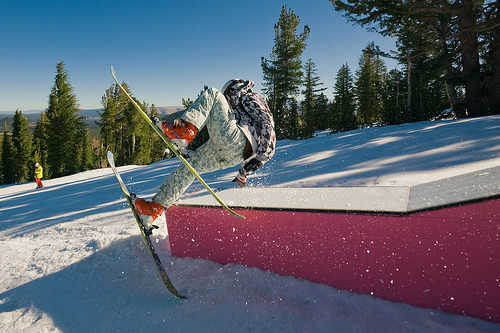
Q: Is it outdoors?
A: Yes, it is outdoors.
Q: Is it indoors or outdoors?
A: It is outdoors.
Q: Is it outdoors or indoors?
A: It is outdoors.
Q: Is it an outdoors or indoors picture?
A: It is outdoors.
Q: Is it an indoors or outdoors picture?
A: It is outdoors.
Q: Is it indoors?
A: No, it is outdoors.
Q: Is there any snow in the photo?
A: Yes, there is snow.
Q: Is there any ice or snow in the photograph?
A: Yes, there is snow.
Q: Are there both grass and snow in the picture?
A: No, there is snow but no grass.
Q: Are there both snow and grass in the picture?
A: No, there is snow but no grass.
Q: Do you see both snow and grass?
A: No, there is snow but no grass.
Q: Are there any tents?
A: No, there are no tents.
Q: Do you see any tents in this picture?
A: No, there are no tents.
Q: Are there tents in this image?
A: No, there are no tents.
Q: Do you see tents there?
A: No, there are no tents.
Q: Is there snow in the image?
A: Yes, there is snow.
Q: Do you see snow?
A: Yes, there is snow.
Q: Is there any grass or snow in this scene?
A: Yes, there is snow.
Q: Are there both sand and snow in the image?
A: No, there is snow but no sand.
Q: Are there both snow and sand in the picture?
A: No, there is snow but no sand.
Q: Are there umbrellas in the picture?
A: No, there are no umbrellas.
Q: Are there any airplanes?
A: No, there are no airplanes.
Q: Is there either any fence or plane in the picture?
A: No, there are no airplanes or fences.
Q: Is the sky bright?
A: Yes, the sky is bright.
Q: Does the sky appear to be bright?
A: Yes, the sky is bright.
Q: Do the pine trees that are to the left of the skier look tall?
A: Yes, the pines are tall.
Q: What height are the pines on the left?
A: The pines are tall.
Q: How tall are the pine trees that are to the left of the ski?
A: The pines are tall.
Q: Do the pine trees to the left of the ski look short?
A: No, the pine trees are tall.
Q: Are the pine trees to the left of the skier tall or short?
A: The pines are tall.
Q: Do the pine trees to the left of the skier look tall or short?
A: The pines are tall.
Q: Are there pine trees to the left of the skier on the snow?
A: Yes, there are pine trees to the left of the skier.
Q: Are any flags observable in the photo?
A: No, there are no flags.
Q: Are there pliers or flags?
A: No, there are no flags or pliers.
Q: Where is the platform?
A: The platform is in the snow.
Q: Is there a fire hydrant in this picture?
A: No, there are no fire hydrants.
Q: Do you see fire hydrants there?
A: No, there are no fire hydrants.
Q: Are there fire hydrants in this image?
A: No, there are no fire hydrants.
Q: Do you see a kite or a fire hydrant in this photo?
A: No, there are no fire hydrants or kites.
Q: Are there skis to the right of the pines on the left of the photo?
A: Yes, there is a ski to the right of the pines.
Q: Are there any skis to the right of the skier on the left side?
A: Yes, there is a ski to the right of the skier.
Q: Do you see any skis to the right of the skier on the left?
A: Yes, there is a ski to the right of the skier.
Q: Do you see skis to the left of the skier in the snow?
A: No, the ski is to the right of the skier.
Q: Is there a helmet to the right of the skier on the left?
A: No, there is a ski to the right of the skier.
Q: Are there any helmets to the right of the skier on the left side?
A: No, there is a ski to the right of the skier.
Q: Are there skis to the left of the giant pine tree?
A: Yes, there is a ski to the left of the pine tree.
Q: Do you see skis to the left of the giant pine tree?
A: Yes, there is a ski to the left of the pine tree.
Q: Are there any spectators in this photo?
A: No, there are no spectators.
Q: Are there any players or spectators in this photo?
A: No, there are no spectators or players.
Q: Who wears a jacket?
A: The skier wears a jacket.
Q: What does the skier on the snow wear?
A: The skier wears a jacket.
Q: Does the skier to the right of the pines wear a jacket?
A: Yes, the skier wears a jacket.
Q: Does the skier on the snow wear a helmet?
A: No, the skier wears a jacket.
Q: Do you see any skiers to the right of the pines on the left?
A: Yes, there is a skier to the right of the pine trees.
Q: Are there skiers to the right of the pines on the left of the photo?
A: Yes, there is a skier to the right of the pine trees.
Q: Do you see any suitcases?
A: No, there are no suitcases.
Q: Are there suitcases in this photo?
A: No, there are no suitcases.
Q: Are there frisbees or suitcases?
A: No, there are no suitcases or frisbees.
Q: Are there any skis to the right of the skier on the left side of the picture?
A: Yes, there is a ski to the right of the skier.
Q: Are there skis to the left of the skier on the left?
A: No, the ski is to the right of the skier.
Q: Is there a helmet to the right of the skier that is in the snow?
A: No, there is a ski to the right of the skier.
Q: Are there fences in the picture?
A: No, there are no fences.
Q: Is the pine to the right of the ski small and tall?
A: No, the pine is tall but giant.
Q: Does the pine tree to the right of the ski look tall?
A: Yes, the pine is tall.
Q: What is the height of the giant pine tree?
A: The pine tree is tall.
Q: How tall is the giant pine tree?
A: The pine is tall.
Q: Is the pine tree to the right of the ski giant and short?
A: No, the pine is giant but tall.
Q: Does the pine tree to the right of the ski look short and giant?
A: No, the pine is giant but tall.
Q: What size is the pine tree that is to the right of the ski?
A: The pine tree is giant.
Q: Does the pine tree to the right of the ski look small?
A: No, the pine is giant.